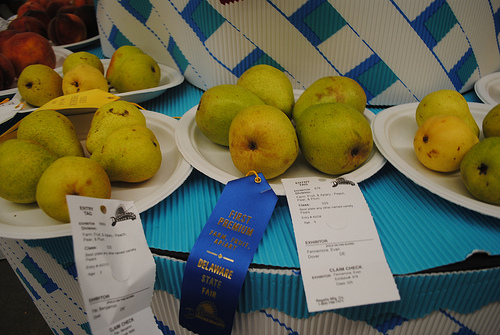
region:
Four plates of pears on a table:
[3, 55, 491, 221]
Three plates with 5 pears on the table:
[1, 22, 378, 230]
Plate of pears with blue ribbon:
[184, 50, 375, 326]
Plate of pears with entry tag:
[284, 31, 380, 302]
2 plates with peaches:
[3, 1, 111, 72]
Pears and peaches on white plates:
[7, 2, 490, 145]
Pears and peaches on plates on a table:
[5, 1, 490, 207]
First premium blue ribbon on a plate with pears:
[190, 55, 285, 327]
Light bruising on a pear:
[297, 71, 353, 121]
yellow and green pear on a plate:
[408, 118, 498, 211]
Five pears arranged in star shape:
[185, 44, 382, 188]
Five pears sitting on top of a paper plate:
[0, 93, 174, 226]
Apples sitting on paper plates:
[0, 1, 107, 87]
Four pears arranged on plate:
[400, 74, 498, 216]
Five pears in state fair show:
[10, 40, 185, 119]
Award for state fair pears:
[174, 158, 274, 333]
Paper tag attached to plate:
[277, 167, 406, 317]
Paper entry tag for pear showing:
[57, 180, 169, 333]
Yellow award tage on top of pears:
[0, 83, 189, 153]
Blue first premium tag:
[174, 163, 283, 333]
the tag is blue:
[175, 159, 269, 333]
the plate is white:
[366, 90, 486, 280]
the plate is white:
[342, 91, 476, 241]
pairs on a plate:
[196, 55, 391, 175]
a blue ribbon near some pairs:
[171, 126, 292, 318]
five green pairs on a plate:
[185, 20, 400, 187]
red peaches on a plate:
[10, 0, 115, 80]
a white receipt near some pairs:
[295, 115, 415, 310]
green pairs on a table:
[0, 40, 440, 330]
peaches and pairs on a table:
[6, 0, 156, 110]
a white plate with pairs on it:
[177, 36, 454, 197]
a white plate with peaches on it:
[14, 2, 119, 84]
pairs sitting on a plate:
[191, 55, 419, 210]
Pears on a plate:
[208, 60, 351, 198]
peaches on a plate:
[10, 19, 64, 77]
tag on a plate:
[285, 161, 389, 317]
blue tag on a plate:
[171, 159, 251, 329]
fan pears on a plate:
[36, 114, 123, 206]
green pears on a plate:
[221, 55, 348, 182]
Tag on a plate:
[58, 175, 170, 328]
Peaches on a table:
[10, 34, 127, 121]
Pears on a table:
[78, 43, 435, 234]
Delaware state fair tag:
[181, 183, 249, 303]